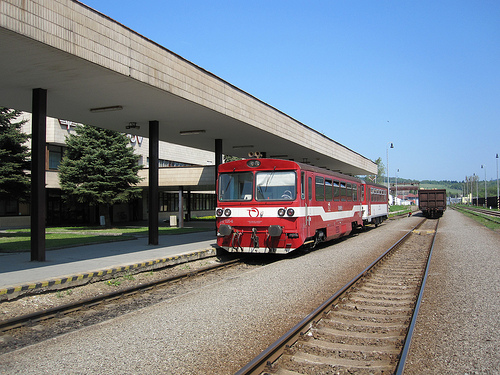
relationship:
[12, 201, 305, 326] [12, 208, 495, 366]
passenger walkway along tracks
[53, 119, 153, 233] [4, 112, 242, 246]
tree near building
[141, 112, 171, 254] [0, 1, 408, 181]
post from ceiling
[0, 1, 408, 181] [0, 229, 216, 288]
ceiling of passenger walkway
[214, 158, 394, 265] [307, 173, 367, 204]
train with windows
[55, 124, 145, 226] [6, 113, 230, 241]
tree in front of building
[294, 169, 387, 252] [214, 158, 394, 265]
side of train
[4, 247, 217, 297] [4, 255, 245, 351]
caution tape by train tracks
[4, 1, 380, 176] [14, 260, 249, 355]
overhang next to train tracks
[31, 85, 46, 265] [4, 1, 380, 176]
post holding up overhang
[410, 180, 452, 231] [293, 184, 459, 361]
train car on train tracks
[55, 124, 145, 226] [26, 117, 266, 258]
tree near building